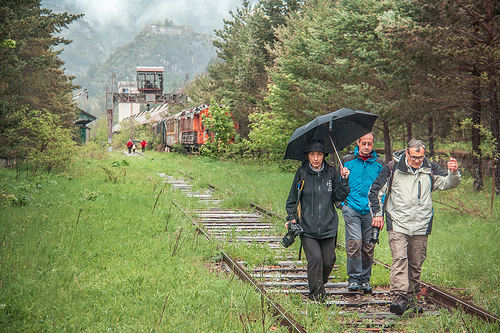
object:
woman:
[283, 138, 351, 303]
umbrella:
[281, 107, 380, 169]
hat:
[302, 138, 330, 157]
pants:
[387, 229, 428, 303]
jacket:
[333, 146, 388, 216]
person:
[140, 139, 147, 152]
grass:
[0, 149, 287, 333]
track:
[145, 170, 287, 247]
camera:
[280, 221, 305, 249]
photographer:
[370, 137, 464, 317]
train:
[151, 102, 239, 155]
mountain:
[76, 17, 217, 108]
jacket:
[126, 141, 132, 148]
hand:
[284, 218, 297, 229]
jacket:
[366, 149, 463, 237]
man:
[332, 131, 389, 294]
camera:
[368, 226, 381, 246]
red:
[140, 140, 147, 148]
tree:
[0, 0, 85, 171]